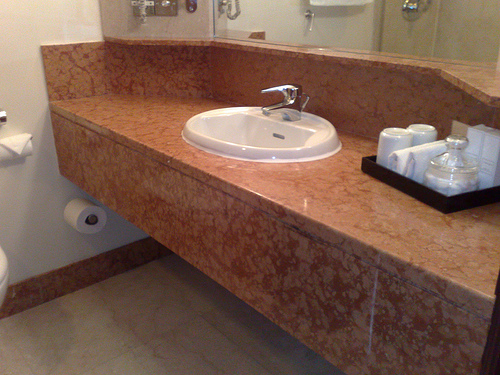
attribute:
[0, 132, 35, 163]
toilet paper — white, rolled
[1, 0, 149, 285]
wall — white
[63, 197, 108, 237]
toilet paper — in roll, spare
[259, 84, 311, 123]
faucet — glossy, silver, turned off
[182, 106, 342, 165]
sink — white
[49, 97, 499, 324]
counter — marble, smooth, brown, reddish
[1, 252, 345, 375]
floor — tiled, stone, tan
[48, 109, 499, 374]
front — marble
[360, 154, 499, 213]
tray — black, little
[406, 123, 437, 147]
cup — white, inverted, for coffee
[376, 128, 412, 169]
cup — white, inverted, for coffee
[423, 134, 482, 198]
jar — small, glass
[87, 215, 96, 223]
handle — metal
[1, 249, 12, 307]
toilet — tan, white